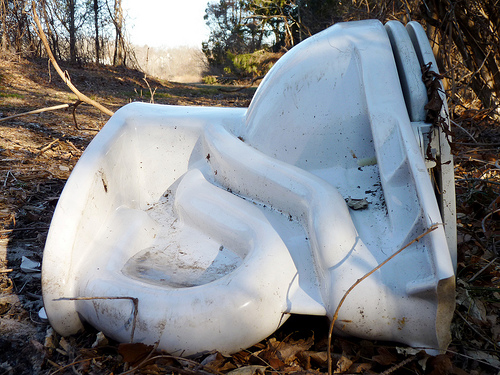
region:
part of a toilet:
[223, 291, 246, 312]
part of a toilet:
[180, 284, 227, 342]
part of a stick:
[301, 305, 343, 344]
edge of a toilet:
[193, 278, 229, 315]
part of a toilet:
[157, 152, 210, 246]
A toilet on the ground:
[42, 23, 465, 355]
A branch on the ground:
[1, 1, 118, 130]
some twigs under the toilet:
[48, 230, 430, 374]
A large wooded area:
[216, 0, 498, 122]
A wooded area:
[3, 0, 123, 66]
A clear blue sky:
[11, 0, 291, 46]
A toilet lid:
[407, 20, 459, 276]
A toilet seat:
[383, 19, 429, 136]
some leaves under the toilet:
[38, 313, 397, 373]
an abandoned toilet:
[41, 13, 459, 353]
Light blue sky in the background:
[44, 0, 271, 45]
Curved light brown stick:
[21, 9, 110, 118]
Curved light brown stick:
[314, 225, 449, 374]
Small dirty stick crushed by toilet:
[49, 286, 149, 352]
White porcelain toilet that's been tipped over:
[36, 15, 460, 359]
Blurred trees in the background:
[132, 42, 202, 82]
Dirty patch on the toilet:
[126, 223, 249, 298]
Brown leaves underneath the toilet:
[20, 325, 478, 371]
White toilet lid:
[381, 12, 474, 294]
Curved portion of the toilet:
[76, 168, 289, 354]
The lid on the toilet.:
[414, 21, 483, 261]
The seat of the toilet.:
[380, 18, 455, 225]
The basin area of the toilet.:
[244, 34, 411, 212]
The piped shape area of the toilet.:
[107, 125, 364, 373]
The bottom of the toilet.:
[41, 64, 211, 291]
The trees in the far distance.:
[107, 16, 214, 76]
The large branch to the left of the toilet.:
[26, 2, 113, 123]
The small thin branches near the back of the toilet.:
[49, 216, 461, 363]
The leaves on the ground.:
[12, 93, 453, 372]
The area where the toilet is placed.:
[33, 89, 499, 368]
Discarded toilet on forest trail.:
[32, 8, 495, 368]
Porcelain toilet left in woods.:
[35, 16, 479, 365]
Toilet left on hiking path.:
[13, 8, 489, 370]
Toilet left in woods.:
[17, 14, 496, 369]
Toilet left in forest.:
[27, 12, 484, 369]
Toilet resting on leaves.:
[27, 14, 497, 361]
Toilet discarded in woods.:
[22, 12, 495, 374]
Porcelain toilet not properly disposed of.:
[23, 10, 498, 367]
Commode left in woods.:
[23, 13, 496, 363]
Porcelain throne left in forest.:
[25, 13, 496, 353]